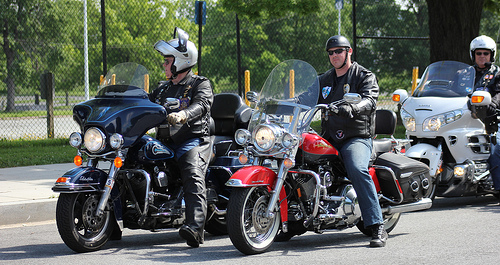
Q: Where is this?
A: This is at the park.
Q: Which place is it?
A: It is a park.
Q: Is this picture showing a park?
A: Yes, it is showing a park.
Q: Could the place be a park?
A: Yes, it is a park.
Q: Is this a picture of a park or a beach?
A: It is showing a park.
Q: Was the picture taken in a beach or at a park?
A: It was taken at a park.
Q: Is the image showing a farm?
A: No, the picture is showing a park.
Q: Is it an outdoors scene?
A: Yes, it is outdoors.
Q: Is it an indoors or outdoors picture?
A: It is outdoors.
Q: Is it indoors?
A: No, it is outdoors.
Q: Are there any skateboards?
A: No, there are no skateboards.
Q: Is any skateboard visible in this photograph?
A: No, there are no skateboards.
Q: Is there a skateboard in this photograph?
A: No, there are no skateboards.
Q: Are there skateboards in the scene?
A: No, there are no skateboards.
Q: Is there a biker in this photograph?
A: Yes, there is a biker.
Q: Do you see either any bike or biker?
A: Yes, there is a biker.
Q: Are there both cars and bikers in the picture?
A: No, there is a biker but no cars.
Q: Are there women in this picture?
A: No, there are no women.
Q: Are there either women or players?
A: No, there are no women or players.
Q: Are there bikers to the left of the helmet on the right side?
A: Yes, there is a biker to the left of the helmet.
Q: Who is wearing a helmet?
A: The biker is wearing a helmet.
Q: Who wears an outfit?
A: The motorcyclist wears an outfit.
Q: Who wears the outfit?
A: The motorcyclist wears an outfit.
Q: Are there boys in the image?
A: No, there are no boys.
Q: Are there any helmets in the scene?
A: Yes, there is a helmet.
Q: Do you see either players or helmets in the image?
A: Yes, there is a helmet.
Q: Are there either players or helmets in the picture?
A: Yes, there is a helmet.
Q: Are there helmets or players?
A: Yes, there is a helmet.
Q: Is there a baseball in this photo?
A: No, there are no baseballs.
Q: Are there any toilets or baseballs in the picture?
A: No, there are no baseballs or toilets.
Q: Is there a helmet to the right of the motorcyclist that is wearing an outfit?
A: Yes, there is a helmet to the right of the motorcyclist.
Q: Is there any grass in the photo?
A: Yes, there is grass.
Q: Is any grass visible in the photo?
A: Yes, there is grass.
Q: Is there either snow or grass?
A: Yes, there is grass.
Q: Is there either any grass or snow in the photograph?
A: Yes, there is grass.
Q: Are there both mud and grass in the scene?
A: No, there is grass but no mud.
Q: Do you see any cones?
A: No, there are no cones.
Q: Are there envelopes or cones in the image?
A: No, there are no cones or envelopes.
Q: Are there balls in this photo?
A: No, there are no balls.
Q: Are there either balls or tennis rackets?
A: No, there are no balls or tennis rackets.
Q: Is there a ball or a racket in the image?
A: No, there are no balls or rackets.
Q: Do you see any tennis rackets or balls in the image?
A: No, there are no balls or tennis rackets.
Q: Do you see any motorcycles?
A: Yes, there is a motorcycle.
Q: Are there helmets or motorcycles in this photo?
A: Yes, there is a motorcycle.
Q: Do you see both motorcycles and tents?
A: No, there is a motorcycle but no tents.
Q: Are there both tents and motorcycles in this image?
A: No, there is a motorcycle but no tents.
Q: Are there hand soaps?
A: No, there are no hand soaps.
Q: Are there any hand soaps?
A: No, there are no hand soaps.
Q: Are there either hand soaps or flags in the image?
A: No, there are no hand soaps or flags.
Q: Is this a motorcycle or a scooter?
A: This is a motorcycle.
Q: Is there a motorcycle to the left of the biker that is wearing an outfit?
A: Yes, there is a motorcycle to the left of the motorcyclist.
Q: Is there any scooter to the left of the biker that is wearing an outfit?
A: No, there is a motorcycle to the left of the motorcyclist.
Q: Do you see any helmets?
A: Yes, there is a helmet.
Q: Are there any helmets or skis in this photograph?
A: Yes, there is a helmet.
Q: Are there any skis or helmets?
A: Yes, there is a helmet.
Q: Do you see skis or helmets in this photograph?
A: Yes, there is a helmet.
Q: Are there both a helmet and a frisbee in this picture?
A: No, there is a helmet but no frisbees.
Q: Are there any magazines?
A: No, there are no magazines.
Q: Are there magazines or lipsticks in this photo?
A: No, there are no magazines or lipsticks.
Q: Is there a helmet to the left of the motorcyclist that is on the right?
A: Yes, there is a helmet to the left of the biker.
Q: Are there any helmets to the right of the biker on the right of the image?
A: No, the helmet is to the left of the motorcyclist.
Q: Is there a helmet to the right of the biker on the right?
A: No, the helmet is to the left of the motorcyclist.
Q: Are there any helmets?
A: Yes, there is a helmet.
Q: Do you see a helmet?
A: Yes, there is a helmet.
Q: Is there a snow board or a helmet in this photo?
A: Yes, there is a helmet.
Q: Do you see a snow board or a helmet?
A: Yes, there is a helmet.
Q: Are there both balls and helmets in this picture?
A: No, there is a helmet but no balls.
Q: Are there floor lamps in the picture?
A: No, there are no floor lamps.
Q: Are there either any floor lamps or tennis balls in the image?
A: No, there are no floor lamps or tennis balls.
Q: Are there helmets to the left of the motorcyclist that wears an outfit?
A: Yes, there is a helmet to the left of the biker.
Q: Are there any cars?
A: No, there are no cars.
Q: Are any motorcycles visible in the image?
A: Yes, there is a motorcycle.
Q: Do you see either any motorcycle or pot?
A: Yes, there is a motorcycle.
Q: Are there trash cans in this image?
A: No, there are no trash cans.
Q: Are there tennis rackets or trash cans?
A: No, there are no trash cans or tennis rackets.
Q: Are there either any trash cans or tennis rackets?
A: No, there are no trash cans or tennis rackets.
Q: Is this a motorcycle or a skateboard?
A: This is a motorcycle.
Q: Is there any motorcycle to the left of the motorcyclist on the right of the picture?
A: Yes, there is a motorcycle to the left of the motorcyclist.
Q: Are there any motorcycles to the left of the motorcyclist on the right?
A: Yes, there is a motorcycle to the left of the motorcyclist.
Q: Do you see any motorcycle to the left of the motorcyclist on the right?
A: Yes, there is a motorcycle to the left of the motorcyclist.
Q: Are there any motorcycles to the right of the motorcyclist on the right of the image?
A: No, the motorcycle is to the left of the biker.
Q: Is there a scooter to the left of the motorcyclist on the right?
A: No, there is a motorcycle to the left of the motorcyclist.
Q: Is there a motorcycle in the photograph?
A: Yes, there is a motorcycle.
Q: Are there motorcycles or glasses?
A: Yes, there is a motorcycle.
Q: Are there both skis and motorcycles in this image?
A: No, there is a motorcycle but no skis.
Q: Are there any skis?
A: No, there are no skis.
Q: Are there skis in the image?
A: No, there are no skis.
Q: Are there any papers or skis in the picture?
A: No, there are no skis or papers.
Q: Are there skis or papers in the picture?
A: No, there are no skis or papers.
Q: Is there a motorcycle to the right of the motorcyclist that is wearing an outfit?
A: Yes, there is a motorcycle to the right of the biker.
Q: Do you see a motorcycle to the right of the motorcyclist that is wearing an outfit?
A: Yes, there is a motorcycle to the right of the biker.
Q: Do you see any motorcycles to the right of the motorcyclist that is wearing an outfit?
A: Yes, there is a motorcycle to the right of the biker.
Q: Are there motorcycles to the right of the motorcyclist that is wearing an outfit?
A: Yes, there is a motorcycle to the right of the biker.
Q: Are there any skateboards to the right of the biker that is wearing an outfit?
A: No, there is a motorcycle to the right of the biker.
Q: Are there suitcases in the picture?
A: No, there are no suitcases.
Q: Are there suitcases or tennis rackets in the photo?
A: No, there are no suitcases or tennis rackets.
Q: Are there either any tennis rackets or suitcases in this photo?
A: No, there are no suitcases or tennis rackets.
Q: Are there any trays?
A: No, there are no trays.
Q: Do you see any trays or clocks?
A: No, there are no trays or clocks.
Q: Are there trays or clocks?
A: No, there are no trays or clocks.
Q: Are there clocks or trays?
A: No, there are no trays or clocks.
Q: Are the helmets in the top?
A: Yes, the helmets are in the top of the image.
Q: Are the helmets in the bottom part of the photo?
A: No, the helmets are in the top of the image.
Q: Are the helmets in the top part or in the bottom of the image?
A: The helmets are in the top of the image.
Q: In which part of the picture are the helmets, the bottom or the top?
A: The helmets are in the top of the image.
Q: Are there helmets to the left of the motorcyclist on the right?
A: Yes, there are helmets to the left of the biker.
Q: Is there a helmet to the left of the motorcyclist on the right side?
A: Yes, there are helmets to the left of the biker.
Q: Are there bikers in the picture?
A: Yes, there is a biker.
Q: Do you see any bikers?
A: Yes, there is a biker.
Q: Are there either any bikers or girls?
A: Yes, there is a biker.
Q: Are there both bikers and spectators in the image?
A: No, there is a biker but no spectators.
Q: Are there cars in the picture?
A: No, there are no cars.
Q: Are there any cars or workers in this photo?
A: No, there are no cars or workers.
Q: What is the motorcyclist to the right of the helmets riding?
A: The motorcyclist is riding a motorcycle.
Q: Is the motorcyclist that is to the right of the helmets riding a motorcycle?
A: Yes, the biker is riding a motorcycle.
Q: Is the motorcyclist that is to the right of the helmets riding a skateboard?
A: No, the motorcyclist is riding a motorcycle.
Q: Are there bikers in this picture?
A: Yes, there is a biker.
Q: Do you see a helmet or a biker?
A: Yes, there is a biker.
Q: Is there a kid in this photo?
A: No, there are no children.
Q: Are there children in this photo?
A: No, there are no children.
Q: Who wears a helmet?
A: The motorcyclist wears a helmet.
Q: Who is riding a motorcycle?
A: The motorcyclist is riding a motorcycle.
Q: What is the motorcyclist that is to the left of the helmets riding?
A: The motorcyclist is riding a motorcycle.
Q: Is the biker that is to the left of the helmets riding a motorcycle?
A: Yes, the motorcyclist is riding a motorcycle.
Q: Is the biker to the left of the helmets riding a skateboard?
A: No, the motorcyclist is riding a motorcycle.